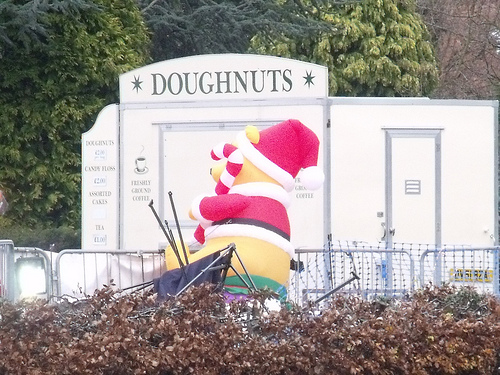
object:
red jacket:
[187, 181, 294, 258]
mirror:
[12, 257, 47, 304]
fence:
[0, 239, 500, 307]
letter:
[167, 72, 183, 95]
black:
[167, 78, 171, 89]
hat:
[236, 119, 321, 193]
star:
[302, 70, 317, 87]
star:
[131, 75, 142, 93]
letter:
[249, 70, 266, 94]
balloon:
[165, 118, 319, 313]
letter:
[214, 71, 232, 95]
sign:
[111, 52, 332, 282]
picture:
[0, 0, 500, 375]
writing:
[77, 135, 119, 247]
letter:
[233, 71, 249, 93]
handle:
[392, 228, 396, 237]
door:
[380, 125, 445, 296]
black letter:
[282, 69, 292, 92]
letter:
[151, 73, 166, 95]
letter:
[266, 69, 282, 92]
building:
[75, 53, 499, 294]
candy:
[210, 144, 241, 196]